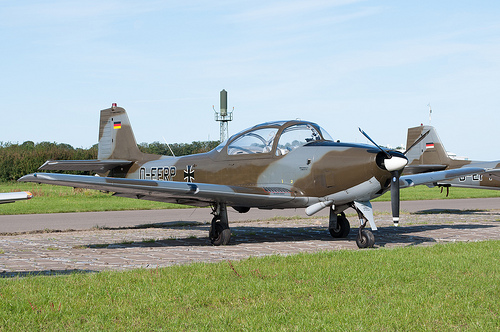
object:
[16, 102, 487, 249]
jet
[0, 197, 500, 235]
runway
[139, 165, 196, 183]
logo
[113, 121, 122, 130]
sticker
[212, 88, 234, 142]
tower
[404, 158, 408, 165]
tip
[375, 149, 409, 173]
nose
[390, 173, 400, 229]
propeller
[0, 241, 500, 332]
grass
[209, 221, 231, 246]
wheel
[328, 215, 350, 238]
wheel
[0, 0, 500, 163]
sky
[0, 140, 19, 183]
tree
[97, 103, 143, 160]
tail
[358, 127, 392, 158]
propeller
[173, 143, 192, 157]
tree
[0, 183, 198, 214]
grass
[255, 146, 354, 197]
paint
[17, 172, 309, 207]
wing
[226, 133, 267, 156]
window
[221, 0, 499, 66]
cloud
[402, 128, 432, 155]
propeller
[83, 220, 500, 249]
shadow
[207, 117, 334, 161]
cockpit